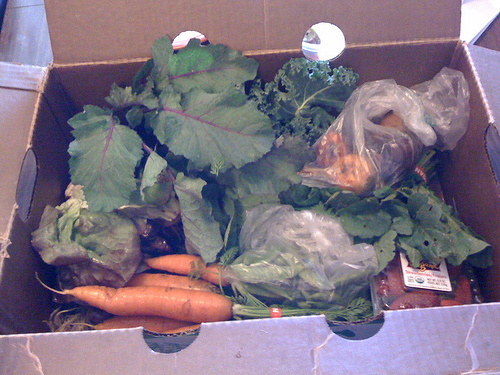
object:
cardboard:
[2, 2, 500, 375]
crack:
[456, 306, 477, 375]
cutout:
[323, 312, 386, 341]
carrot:
[35, 285, 377, 328]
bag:
[237, 202, 380, 308]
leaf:
[66, 103, 142, 211]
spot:
[107, 293, 113, 299]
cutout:
[142, 321, 201, 353]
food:
[40, 34, 489, 316]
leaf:
[399, 193, 490, 270]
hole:
[424, 240, 429, 246]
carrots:
[136, 254, 270, 286]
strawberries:
[388, 290, 438, 312]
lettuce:
[254, 54, 357, 142]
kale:
[337, 195, 390, 239]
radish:
[381, 113, 402, 128]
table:
[1, 1, 500, 375]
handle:
[13, 144, 39, 225]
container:
[367, 258, 483, 313]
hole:
[302, 20, 346, 65]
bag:
[300, 68, 470, 201]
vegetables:
[252, 181, 270, 198]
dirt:
[182, 297, 191, 323]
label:
[400, 249, 453, 294]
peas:
[119, 244, 130, 253]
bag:
[27, 203, 141, 291]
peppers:
[325, 155, 376, 187]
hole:
[169, 32, 208, 55]